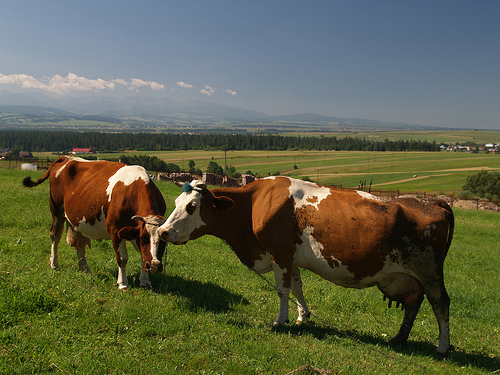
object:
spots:
[281, 176, 334, 214]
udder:
[396, 301, 405, 313]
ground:
[0, 149, 498, 374]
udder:
[385, 295, 393, 311]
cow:
[155, 173, 456, 360]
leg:
[387, 291, 425, 337]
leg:
[283, 266, 309, 317]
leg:
[62, 228, 91, 269]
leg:
[44, 215, 63, 263]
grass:
[0, 166, 499, 374]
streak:
[141, 213, 161, 265]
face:
[127, 219, 169, 279]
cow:
[21, 154, 172, 293]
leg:
[426, 275, 450, 352]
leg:
[272, 255, 291, 320]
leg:
[111, 232, 127, 286]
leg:
[136, 273, 153, 287]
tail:
[19, 157, 60, 188]